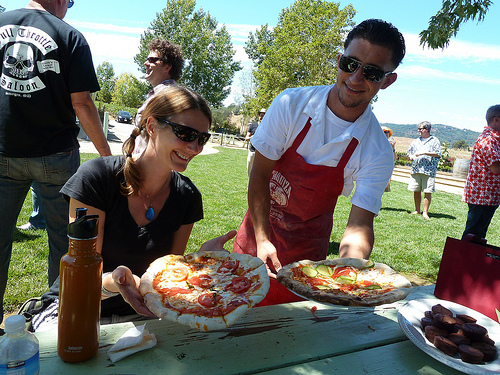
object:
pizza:
[276, 256, 414, 309]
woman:
[32, 81, 238, 333]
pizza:
[139, 249, 271, 333]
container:
[56, 207, 104, 367]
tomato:
[188, 274, 215, 290]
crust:
[193, 316, 227, 333]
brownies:
[432, 313, 456, 329]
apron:
[230, 116, 360, 309]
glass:
[159, 119, 211, 147]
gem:
[145, 206, 156, 221]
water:
[0, 313, 40, 375]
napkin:
[107, 323, 159, 364]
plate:
[396, 298, 499, 374]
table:
[0, 284, 499, 373]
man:
[230, 17, 407, 308]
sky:
[0, 0, 499, 133]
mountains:
[378, 122, 481, 161]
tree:
[238, 0, 379, 138]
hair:
[120, 78, 214, 198]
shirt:
[0, 7, 102, 160]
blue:
[144, 206, 155, 221]